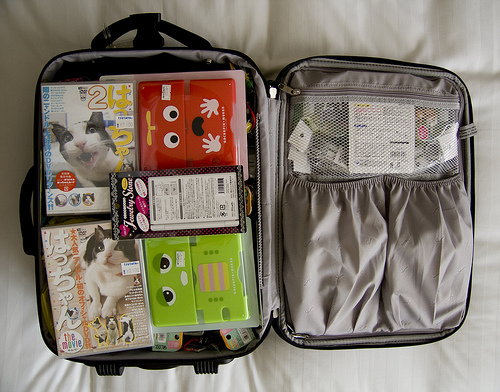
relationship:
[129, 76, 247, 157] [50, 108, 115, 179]
dvd with cat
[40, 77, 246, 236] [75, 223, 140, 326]
case with cat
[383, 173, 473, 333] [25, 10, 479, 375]
pocket on suitcase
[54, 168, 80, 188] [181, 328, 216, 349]
tag with hole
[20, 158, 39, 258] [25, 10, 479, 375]
handle of suitcase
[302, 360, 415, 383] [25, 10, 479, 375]
sheet under suitcase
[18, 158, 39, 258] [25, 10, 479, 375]
handle on suitcase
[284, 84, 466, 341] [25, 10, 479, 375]
compartment inside suitcase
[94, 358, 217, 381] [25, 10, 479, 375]
wheels on suitcase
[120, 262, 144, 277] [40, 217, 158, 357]
sticker on dvd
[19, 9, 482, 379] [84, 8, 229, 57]
luggage has handle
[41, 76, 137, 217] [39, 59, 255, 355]
dvd about cats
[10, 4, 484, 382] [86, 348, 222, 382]
luggage has wheels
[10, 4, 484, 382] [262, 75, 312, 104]
luggage has zippers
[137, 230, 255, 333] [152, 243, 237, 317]
disk holder has silly face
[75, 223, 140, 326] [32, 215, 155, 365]
cat on magazine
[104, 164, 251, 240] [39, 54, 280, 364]
cards in pack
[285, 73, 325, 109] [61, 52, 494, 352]
zipper on bag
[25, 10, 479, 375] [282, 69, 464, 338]
suitcase has lining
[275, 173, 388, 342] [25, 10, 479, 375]
pocket inside suitcase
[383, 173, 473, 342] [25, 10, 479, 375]
pocket inside suitcase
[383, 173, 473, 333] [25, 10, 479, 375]
pocket inside suitcase